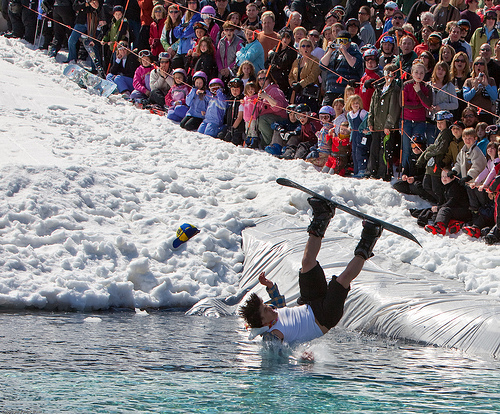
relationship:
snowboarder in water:
[244, 176, 423, 365] [8, 307, 499, 413]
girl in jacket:
[371, 67, 399, 171] [375, 85, 402, 132]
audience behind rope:
[5, 4, 499, 239] [24, 1, 499, 189]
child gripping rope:
[173, 72, 226, 132] [24, 1, 499, 189]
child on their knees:
[173, 72, 226, 132] [170, 103, 217, 140]